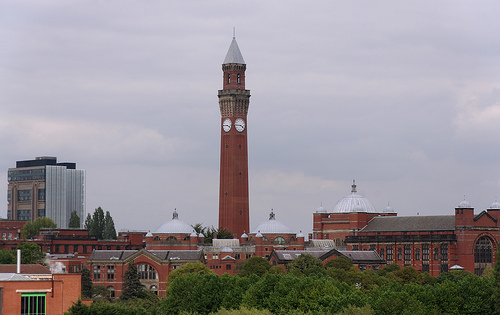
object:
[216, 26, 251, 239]
tower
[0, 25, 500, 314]
town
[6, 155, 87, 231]
building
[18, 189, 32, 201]
window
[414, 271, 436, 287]
trees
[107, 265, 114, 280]
window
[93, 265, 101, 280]
window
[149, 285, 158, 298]
window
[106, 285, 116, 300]
window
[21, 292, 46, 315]
window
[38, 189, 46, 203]
window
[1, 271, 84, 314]
building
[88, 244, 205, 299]
building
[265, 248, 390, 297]
building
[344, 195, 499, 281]
building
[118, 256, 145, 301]
tree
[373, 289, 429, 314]
tree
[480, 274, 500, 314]
tree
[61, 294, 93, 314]
tree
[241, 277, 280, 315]
tree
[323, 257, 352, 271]
trees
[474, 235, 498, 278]
window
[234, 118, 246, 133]
clock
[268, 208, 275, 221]
point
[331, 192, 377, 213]
dome roof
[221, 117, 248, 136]
clock area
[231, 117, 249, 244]
wall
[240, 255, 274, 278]
trees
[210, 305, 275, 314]
shrubs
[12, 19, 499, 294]
building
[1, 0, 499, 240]
grey sky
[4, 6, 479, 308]
photo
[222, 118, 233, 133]
clocks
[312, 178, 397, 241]
building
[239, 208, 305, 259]
building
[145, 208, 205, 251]
building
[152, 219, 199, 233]
roof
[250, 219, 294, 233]
roof